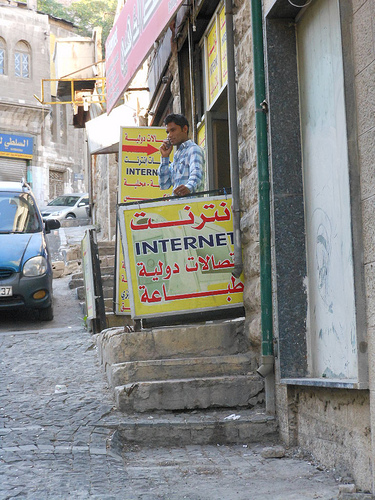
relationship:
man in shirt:
[158, 112, 206, 198] [155, 133, 205, 195]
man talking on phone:
[119, 112, 211, 198] [164, 135, 177, 143]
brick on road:
[263, 444, 284, 461] [25, 339, 94, 473]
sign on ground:
[113, 195, 244, 335] [93, 313, 247, 369]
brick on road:
[46, 433, 67, 445] [9, 345, 129, 499]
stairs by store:
[96, 315, 282, 450] [111, 23, 371, 378]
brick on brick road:
[49, 377, 72, 398] [0, 276, 343, 498]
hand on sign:
[171, 186, 189, 195] [114, 194, 246, 317]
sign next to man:
[117, 193, 247, 321] [122, 104, 218, 304]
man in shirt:
[158, 112, 206, 198] [142, 143, 207, 201]